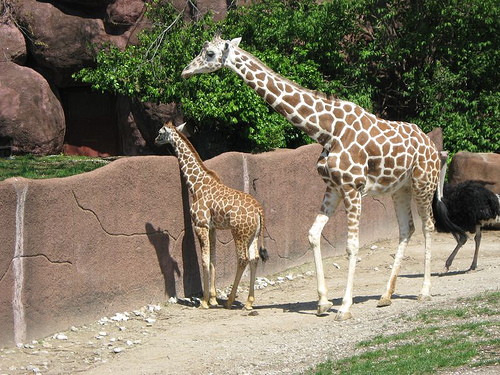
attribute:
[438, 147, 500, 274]
ostrich — white, black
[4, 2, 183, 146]
rocks — brown, grey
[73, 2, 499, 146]
trees — green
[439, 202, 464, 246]
tuft — brown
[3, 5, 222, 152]
wall — brown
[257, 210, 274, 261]
tail — black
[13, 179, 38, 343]
stain — white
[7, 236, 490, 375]
ground — rocky